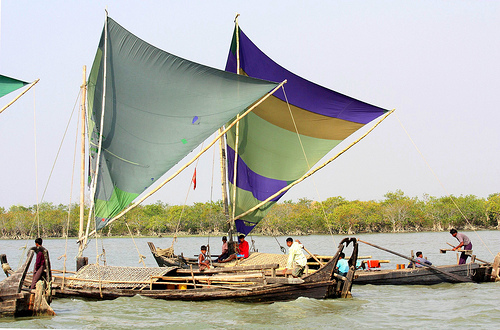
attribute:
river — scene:
[364, 287, 459, 329]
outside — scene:
[3, 6, 494, 328]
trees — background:
[293, 201, 434, 233]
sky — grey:
[3, 5, 498, 202]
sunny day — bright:
[5, 3, 498, 328]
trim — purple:
[223, 30, 386, 127]